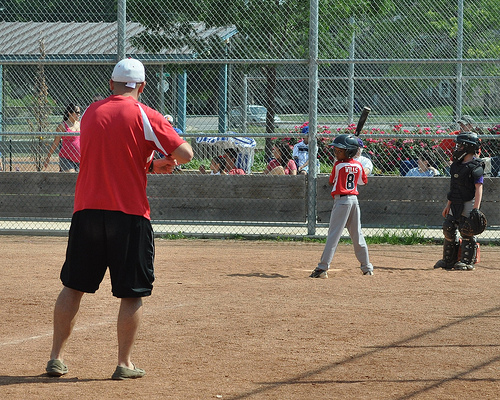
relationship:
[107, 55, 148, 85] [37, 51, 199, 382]
hat on coach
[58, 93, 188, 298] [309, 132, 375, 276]
baseball uniform worn by player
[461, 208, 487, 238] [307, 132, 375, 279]
mitt on child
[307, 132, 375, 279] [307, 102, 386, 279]
child holding baseball bat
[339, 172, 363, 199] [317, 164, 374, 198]
number on back of jersey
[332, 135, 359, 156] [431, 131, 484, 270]
helmet on boy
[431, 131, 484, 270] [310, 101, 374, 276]
boy standing behind batter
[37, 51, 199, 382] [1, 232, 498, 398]
coach standing in field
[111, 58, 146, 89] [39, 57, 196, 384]
hat on man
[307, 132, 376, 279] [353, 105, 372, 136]
child waiting to baseball bat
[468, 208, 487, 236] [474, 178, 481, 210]
mitt on hand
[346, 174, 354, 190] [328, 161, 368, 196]
number on shirt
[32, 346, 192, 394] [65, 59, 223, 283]
loafers on baseball coach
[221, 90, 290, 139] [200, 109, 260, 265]
car behind fence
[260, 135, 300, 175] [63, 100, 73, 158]
woman in shirt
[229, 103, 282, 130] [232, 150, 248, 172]
car in parking lot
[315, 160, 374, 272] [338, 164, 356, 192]
uniform has number eight on back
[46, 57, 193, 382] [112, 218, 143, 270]
coach dressed in red and black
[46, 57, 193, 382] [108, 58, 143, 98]
coach wearing hat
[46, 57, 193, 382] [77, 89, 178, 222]
coach wearing shirt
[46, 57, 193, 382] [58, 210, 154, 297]
coach wearing shorts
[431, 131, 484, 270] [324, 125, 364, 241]
boy wearing helmet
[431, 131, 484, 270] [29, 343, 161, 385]
boy wearing shoes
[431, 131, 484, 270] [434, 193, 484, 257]
boy has mitt on left hand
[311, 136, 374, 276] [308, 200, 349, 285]
batter has leg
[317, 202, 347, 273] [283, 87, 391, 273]
leg belonging to batter